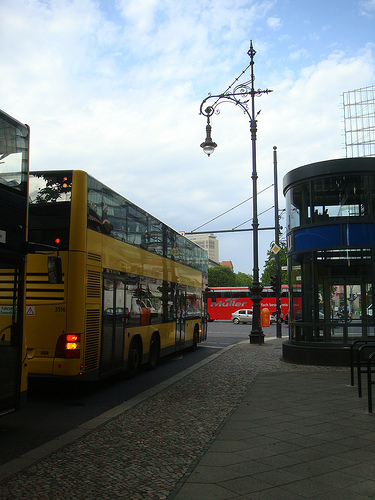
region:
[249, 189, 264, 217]
part of a post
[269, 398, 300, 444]
part of a walkpath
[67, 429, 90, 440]
edge of a road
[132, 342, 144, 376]
part of a rim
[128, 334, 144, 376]
part of a wheel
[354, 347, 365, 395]
part of a metal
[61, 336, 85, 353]
part of a backlight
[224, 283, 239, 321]
side of a bus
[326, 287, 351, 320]
part of a window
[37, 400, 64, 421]
part of a road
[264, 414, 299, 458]
part of a walk way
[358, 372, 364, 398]
part of a post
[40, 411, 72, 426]
part of a road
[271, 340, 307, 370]
edge of a building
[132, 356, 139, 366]
part of a rim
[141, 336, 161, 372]
part of a wheel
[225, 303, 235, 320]
edge of a car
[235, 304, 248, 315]
window of a car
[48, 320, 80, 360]
part of a backlight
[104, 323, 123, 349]
part of a door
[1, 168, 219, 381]
Bus parked next to light post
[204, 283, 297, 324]
Red bus across golden yellow bus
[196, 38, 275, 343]
Light post is black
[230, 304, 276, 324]
Gray car next to red bus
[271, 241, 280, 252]
Diamond shaped sign on light post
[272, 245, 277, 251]
Yellow diamond on diamond sign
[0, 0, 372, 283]
Sky is blue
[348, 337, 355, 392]
Black pole on sidewalk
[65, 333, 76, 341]
Light on bus is red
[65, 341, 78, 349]
Light on bus is orange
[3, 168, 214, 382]
a large yellow double decker bus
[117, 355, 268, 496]
the sidewalk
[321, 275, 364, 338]
the entrance to a round glass building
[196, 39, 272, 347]
a tall lamppost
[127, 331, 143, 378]
the wheel of a bus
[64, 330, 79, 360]
a taillight of a bus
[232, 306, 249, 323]
a silver car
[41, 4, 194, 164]
a cloudy sky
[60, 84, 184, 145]
cloud coverage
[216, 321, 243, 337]
a city street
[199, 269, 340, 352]
red double decker bus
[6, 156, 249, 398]
yellow double decker bus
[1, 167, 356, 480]
street scene with buses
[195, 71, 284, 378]
fancy street lamp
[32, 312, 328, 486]
cobble stone side walk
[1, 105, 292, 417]
busy road with buses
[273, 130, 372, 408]
entrance to bus station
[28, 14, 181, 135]
blue sky with white clouds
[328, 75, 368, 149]
scaffolding of construction project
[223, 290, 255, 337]
muller logo on red bus